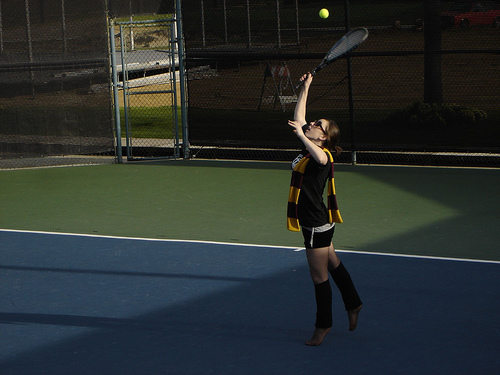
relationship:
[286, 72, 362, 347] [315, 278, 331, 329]
woman wearing leg warmer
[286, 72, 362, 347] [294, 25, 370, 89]
woman holding racquet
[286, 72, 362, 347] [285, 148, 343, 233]
woman wearing scarf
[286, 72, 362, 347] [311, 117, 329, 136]
woman wearing sunglasses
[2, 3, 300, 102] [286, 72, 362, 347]
gate behind woman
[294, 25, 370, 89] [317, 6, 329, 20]
racquet hitting tennis ball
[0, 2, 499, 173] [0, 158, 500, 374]
fence next to tennis court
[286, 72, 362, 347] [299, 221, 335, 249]
woman wearing shorts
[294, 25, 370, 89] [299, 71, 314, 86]
racquet in hand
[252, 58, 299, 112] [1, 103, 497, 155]
traffic sawhorse on grass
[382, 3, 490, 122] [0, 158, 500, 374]
tree behind tennis court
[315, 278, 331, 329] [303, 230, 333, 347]
leg warmer on leg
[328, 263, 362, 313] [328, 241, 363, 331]
leg warmer on leg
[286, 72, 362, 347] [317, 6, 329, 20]
woman hitting tennis ball